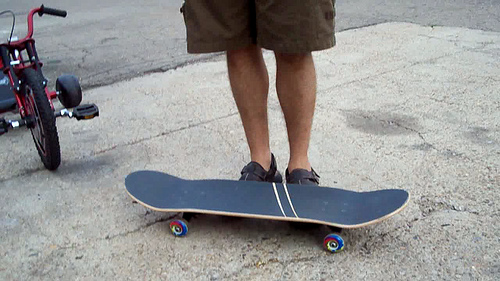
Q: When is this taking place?
A: Daytime.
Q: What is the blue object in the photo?
A: Skateboard.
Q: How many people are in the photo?
A: One.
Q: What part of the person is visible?
A: Legs and feet.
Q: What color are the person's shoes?
A: Black.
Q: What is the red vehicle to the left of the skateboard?
A: Tricycle.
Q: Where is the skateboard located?
A: Cement ground.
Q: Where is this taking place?
A: On a sidewalk of a street.